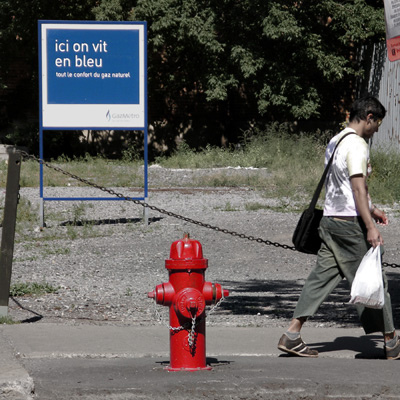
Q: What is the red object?
A: Fire hydrant.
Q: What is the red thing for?
A: Fire fighting.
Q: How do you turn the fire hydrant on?
A: Turn the top.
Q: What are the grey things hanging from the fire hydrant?
A: Chains.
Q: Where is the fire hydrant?
A: Sidewalk.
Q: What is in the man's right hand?
A: Bag.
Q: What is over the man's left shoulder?
A: Black bag.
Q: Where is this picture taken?
A: A street.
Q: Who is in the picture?
A: A man.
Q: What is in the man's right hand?
A: A bag.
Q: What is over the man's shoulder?
A: A satchel.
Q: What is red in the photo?
A: A fire hydrant.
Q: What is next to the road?
A: Gravel.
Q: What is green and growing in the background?
A: Trees.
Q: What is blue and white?
A: A sign.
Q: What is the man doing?
A: Walking.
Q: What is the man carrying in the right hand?
A: A white bag.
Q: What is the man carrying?
A: A bag.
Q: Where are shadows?
A: On the ground.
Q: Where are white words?
A: On a sign.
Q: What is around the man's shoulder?
A: A black bag.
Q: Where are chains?
A: On a fire hydrant.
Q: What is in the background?
A: Trees.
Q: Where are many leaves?
A: On the trees.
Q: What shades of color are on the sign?
A: Blue and white.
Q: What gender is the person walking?
A: Male.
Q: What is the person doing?
A: Walking.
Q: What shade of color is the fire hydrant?
A: Red.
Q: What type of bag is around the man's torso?
A: Messenger.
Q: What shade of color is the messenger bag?
A: Black.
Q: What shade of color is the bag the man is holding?
A: White.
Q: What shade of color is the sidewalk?
A: Gray.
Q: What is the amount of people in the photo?
A: 1.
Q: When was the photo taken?
A: Afternoon.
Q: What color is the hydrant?
A: Red.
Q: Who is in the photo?
A: A guy.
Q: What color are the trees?
A: Green.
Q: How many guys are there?
A: One.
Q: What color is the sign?
A: Blue.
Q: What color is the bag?
A: White.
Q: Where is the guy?
A: On the street.